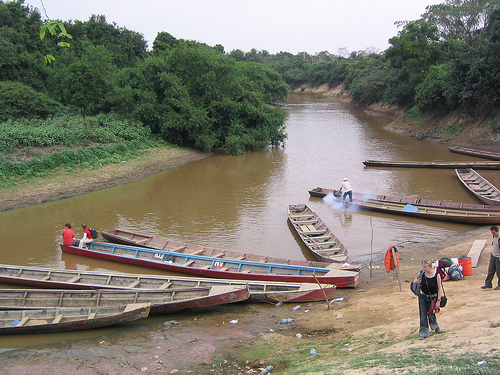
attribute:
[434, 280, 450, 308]
purse — black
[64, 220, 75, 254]
shirt — red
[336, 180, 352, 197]
shirt — white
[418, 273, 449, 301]
top — black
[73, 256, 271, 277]
canoe — red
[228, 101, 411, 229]
water — brown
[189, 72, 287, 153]
trees — green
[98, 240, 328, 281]
railing — blue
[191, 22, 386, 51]
sky — cloudy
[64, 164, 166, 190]
dirt — brown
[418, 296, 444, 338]
pants — blue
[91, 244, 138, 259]
frame — blue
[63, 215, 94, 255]
people — sitting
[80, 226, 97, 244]
shirt — red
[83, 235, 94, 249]
pants — white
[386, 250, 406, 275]
jacket — orange, puffy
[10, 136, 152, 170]
shrubs — green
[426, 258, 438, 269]
hair — blonde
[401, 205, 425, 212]
shopping bag — blue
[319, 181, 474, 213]
boat — long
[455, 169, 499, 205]
boat — grey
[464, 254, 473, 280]
bucket — orange, big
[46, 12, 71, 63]
leaves — bright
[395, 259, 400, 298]
pole — wooden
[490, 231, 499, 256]
shirt — gray